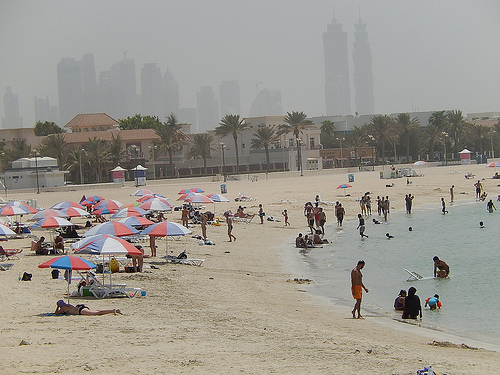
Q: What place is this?
A: It is a beach.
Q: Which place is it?
A: It is a beach.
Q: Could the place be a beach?
A: Yes, it is a beach.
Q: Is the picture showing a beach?
A: Yes, it is showing a beach.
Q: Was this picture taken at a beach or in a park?
A: It was taken at a beach.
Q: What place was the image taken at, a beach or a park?
A: It was taken at a beach.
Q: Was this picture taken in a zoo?
A: No, the picture was taken in a beach.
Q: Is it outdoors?
A: Yes, it is outdoors.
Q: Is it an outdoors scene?
A: Yes, it is outdoors.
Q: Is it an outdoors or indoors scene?
A: It is outdoors.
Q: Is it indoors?
A: No, it is outdoors.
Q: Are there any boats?
A: No, there are no boats.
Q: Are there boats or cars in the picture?
A: No, there are no boats or cars.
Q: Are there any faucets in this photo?
A: No, there are no faucets.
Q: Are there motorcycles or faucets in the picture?
A: No, there are no faucets or motorcycles.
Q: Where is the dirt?
A: The dirt is on the beach.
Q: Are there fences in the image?
A: No, there are no fences.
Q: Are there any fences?
A: No, there are no fences.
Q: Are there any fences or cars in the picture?
A: No, there are no fences or cars.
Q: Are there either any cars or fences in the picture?
A: No, there are no fences or cars.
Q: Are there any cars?
A: No, there are no cars.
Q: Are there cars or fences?
A: No, there are no cars or fences.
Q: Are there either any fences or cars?
A: No, there are no cars or fences.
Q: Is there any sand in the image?
A: Yes, there is sand.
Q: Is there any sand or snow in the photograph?
A: Yes, there is sand.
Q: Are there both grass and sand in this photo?
A: No, there is sand but no grass.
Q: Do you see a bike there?
A: No, there are no bikes.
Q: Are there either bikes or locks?
A: No, there are no bikes or locks.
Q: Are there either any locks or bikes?
A: No, there are no bikes or locks.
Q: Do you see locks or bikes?
A: No, there are no bikes or locks.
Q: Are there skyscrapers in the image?
A: Yes, there is a skyscraper.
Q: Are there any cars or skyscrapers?
A: Yes, there is a skyscraper.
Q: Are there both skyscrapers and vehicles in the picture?
A: No, there is a skyscraper but no vehicles.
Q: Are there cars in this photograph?
A: No, there are no cars.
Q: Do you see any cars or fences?
A: No, there are no cars or fences.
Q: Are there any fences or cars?
A: No, there are no cars or fences.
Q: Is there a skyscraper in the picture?
A: Yes, there is a skyscraper.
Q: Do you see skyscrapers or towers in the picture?
A: Yes, there is a skyscraper.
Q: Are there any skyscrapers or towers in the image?
A: Yes, there is a skyscraper.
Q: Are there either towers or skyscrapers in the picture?
A: Yes, there is a skyscraper.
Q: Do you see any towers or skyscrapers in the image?
A: Yes, there is a skyscraper.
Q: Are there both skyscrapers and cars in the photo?
A: No, there is a skyscraper but no cars.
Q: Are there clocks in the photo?
A: No, there are no clocks.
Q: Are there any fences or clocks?
A: No, there are no clocks or fences.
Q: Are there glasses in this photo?
A: No, there are no glasses.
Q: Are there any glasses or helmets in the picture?
A: No, there are no glasses or helmets.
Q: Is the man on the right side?
A: Yes, the man is on the right of the image.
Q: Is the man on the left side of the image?
A: No, the man is on the right of the image.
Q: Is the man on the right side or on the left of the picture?
A: The man is on the right of the image.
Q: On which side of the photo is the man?
A: The man is on the right of the image.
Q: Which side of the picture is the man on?
A: The man is on the right of the image.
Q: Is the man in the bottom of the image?
A: Yes, the man is in the bottom of the image.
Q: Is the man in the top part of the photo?
A: No, the man is in the bottom of the image.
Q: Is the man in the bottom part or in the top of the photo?
A: The man is in the bottom of the image.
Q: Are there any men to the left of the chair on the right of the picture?
A: Yes, there is a man to the left of the chair.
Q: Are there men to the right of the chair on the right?
A: No, the man is to the left of the chair.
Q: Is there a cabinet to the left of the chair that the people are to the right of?
A: No, there is a man to the left of the chair.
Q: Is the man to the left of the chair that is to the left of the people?
A: Yes, the man is to the left of the chair.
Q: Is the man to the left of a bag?
A: No, the man is to the left of the chair.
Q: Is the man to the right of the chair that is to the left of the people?
A: No, the man is to the left of the chair.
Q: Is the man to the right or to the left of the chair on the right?
A: The man is to the left of the chair.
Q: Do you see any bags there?
A: No, there are no bags.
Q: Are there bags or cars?
A: No, there are no bags or cars.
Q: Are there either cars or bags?
A: No, there are no bags or cars.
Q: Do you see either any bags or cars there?
A: No, there are no bags or cars.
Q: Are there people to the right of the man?
A: Yes, there are people to the right of the man.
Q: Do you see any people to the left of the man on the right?
A: No, the people are to the right of the man.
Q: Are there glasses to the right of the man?
A: No, there are people to the right of the man.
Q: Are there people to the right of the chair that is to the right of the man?
A: Yes, there are people to the right of the chair.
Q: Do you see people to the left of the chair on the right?
A: No, the people are to the right of the chair.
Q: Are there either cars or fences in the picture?
A: No, there are no cars or fences.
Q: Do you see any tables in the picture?
A: No, there are no tables.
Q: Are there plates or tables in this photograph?
A: No, there are no tables or plates.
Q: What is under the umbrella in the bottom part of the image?
A: The chairs are under the umbrella.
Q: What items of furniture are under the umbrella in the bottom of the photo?
A: The pieces of furniture are chairs.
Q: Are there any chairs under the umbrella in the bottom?
A: Yes, there are chairs under the umbrella.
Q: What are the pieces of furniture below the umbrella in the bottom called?
A: The pieces of furniture are chairs.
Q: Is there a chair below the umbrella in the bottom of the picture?
A: Yes, there are chairs below the umbrella.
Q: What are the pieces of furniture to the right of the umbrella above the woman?
A: The pieces of furniture are chairs.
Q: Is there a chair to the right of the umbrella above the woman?
A: Yes, there are chairs to the right of the umbrella.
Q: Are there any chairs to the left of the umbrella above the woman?
A: No, the chairs are to the right of the umbrella.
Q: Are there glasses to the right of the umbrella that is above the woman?
A: No, there are chairs to the right of the umbrella.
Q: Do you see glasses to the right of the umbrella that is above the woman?
A: No, there are chairs to the right of the umbrella.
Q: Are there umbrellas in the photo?
A: Yes, there is an umbrella.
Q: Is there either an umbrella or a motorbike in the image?
A: Yes, there is an umbrella.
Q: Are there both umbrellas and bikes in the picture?
A: No, there is an umbrella but no bikes.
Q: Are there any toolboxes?
A: No, there are no toolboxes.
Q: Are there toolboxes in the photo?
A: No, there are no toolboxes.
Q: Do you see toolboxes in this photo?
A: No, there are no toolboxes.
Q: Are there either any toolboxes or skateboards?
A: No, there are no toolboxes or skateboards.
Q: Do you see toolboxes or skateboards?
A: No, there are no toolboxes or skateboards.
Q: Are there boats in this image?
A: No, there are no boats.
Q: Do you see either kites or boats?
A: No, there are no boats or kites.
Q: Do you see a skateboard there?
A: No, there are no skateboards.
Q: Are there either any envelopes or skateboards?
A: No, there are no skateboards or envelopes.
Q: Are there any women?
A: Yes, there is a woman.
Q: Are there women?
A: Yes, there is a woman.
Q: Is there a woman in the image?
A: Yes, there is a woman.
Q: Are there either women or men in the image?
A: Yes, there is a woman.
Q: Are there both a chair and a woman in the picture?
A: Yes, there are both a woman and a chair.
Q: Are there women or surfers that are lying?
A: Yes, the woman is lying.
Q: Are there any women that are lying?
A: Yes, there is a woman that is lying.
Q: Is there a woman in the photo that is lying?
A: Yes, there is a woman that is lying.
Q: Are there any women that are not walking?
A: Yes, there is a woman that is lying.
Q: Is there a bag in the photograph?
A: No, there are no bags.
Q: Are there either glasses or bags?
A: No, there are no bags or glasses.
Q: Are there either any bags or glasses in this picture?
A: No, there are no bags or glasses.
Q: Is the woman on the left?
A: Yes, the woman is on the left of the image.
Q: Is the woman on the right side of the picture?
A: No, the woman is on the left of the image.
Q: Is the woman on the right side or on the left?
A: The woman is on the left of the image.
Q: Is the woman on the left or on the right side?
A: The woman is on the left of the image.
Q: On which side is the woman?
A: The woman is on the left of the image.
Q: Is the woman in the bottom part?
A: Yes, the woman is in the bottom of the image.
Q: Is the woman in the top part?
A: No, the woman is in the bottom of the image.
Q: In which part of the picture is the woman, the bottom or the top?
A: The woman is in the bottom of the image.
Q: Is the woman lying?
A: Yes, the woman is lying.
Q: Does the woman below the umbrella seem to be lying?
A: Yes, the woman is lying.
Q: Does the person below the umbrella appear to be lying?
A: Yes, the woman is lying.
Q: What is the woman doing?
A: The woman is lying.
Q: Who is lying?
A: The woman is lying.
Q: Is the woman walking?
A: No, the woman is lying.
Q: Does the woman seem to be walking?
A: No, the woman is lying.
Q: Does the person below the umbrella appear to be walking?
A: No, the woman is lying.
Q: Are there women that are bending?
A: No, there is a woman but she is lying.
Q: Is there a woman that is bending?
A: No, there is a woman but she is lying.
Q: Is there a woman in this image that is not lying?
A: No, there is a woman but she is lying.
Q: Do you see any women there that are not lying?
A: No, there is a woman but she is lying.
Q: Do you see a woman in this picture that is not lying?
A: No, there is a woman but she is lying.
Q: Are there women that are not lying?
A: No, there is a woman but she is lying.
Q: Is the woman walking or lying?
A: The woman is lying.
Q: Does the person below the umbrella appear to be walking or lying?
A: The woman is lying.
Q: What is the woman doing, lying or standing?
A: The woman is lying.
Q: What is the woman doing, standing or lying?
A: The woman is lying.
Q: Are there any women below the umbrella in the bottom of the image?
A: Yes, there is a woman below the umbrella.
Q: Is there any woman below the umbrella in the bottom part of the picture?
A: Yes, there is a woman below the umbrella.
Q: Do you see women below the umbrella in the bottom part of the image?
A: Yes, there is a woman below the umbrella.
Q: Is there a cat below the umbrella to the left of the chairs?
A: No, there is a woman below the umbrella.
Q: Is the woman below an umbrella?
A: Yes, the woman is below an umbrella.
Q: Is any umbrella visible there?
A: Yes, there is an umbrella.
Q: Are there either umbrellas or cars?
A: Yes, there is an umbrella.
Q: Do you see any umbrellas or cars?
A: Yes, there is an umbrella.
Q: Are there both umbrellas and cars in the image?
A: No, there is an umbrella but no cars.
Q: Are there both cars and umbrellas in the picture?
A: No, there is an umbrella but no cars.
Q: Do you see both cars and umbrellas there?
A: No, there is an umbrella but no cars.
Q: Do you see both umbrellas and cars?
A: No, there is an umbrella but no cars.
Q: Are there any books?
A: No, there are no books.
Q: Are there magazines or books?
A: No, there are no books or magazines.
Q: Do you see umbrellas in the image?
A: Yes, there is an umbrella.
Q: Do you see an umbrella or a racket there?
A: Yes, there is an umbrella.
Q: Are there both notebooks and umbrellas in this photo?
A: No, there is an umbrella but no notebooks.